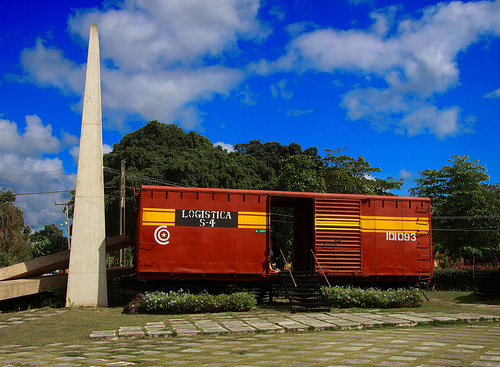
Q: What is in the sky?
A: White clouds.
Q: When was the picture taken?
A: During the daytime.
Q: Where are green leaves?
A: On many trees.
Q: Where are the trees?
A: In the distance.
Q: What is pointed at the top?
A: A monument.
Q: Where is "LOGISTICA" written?
A: On building.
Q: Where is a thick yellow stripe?
A: On the building.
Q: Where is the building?
A: Next to a monument.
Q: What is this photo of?
A: A parking lot.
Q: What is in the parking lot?
A: A trailer.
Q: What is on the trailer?
A: Numbers.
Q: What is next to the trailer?
A: A tall statue.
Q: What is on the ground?
A: Stone.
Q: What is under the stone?
A: Green grass.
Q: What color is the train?
A: Red.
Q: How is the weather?
A: Clear.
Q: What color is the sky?
A: Blue.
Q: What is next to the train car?
A: A sculpture.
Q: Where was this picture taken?
A: A park.